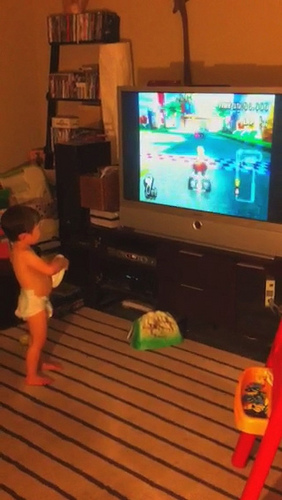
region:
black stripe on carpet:
[75, 310, 245, 372]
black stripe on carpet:
[52, 313, 237, 382]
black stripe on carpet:
[48, 325, 234, 399]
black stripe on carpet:
[46, 336, 232, 415]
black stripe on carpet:
[1, 363, 279, 498]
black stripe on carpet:
[0, 377, 230, 498]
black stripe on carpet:
[3, 401, 180, 497]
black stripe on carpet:
[0, 423, 127, 499]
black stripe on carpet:
[1, 452, 72, 499]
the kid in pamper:
[3, 206, 66, 386]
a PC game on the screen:
[123, 93, 280, 242]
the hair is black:
[1, 205, 42, 241]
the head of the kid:
[2, 206, 41, 246]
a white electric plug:
[265, 281, 275, 308]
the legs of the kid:
[24, 316, 61, 386]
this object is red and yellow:
[230, 327, 281, 496]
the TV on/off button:
[192, 221, 201, 229]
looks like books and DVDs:
[47, 12, 97, 143]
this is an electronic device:
[107, 243, 156, 267]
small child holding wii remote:
[1, 205, 72, 392]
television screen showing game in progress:
[115, 83, 279, 219]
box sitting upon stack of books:
[78, 165, 123, 230]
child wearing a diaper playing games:
[2, 205, 74, 388]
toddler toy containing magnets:
[230, 305, 281, 496]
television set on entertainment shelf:
[82, 76, 280, 352]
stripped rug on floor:
[1, 307, 273, 496]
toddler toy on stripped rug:
[124, 307, 190, 355]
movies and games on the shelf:
[43, 10, 119, 43]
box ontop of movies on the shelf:
[51, 117, 80, 130]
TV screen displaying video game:
[113, 83, 280, 259]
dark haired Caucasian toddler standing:
[3, 202, 69, 386]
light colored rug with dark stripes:
[10, 402, 228, 495]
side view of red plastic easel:
[229, 311, 281, 497]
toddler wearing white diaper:
[1, 201, 66, 325]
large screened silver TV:
[118, 83, 281, 258]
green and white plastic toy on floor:
[123, 307, 183, 352]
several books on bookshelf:
[32, 4, 118, 143]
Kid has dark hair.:
[3, 216, 41, 236]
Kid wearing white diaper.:
[7, 291, 55, 317]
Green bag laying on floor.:
[131, 315, 196, 346]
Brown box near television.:
[77, 170, 127, 212]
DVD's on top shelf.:
[42, 21, 121, 38]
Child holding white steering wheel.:
[50, 251, 82, 284]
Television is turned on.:
[152, 147, 223, 196]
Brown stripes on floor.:
[86, 412, 163, 489]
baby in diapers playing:
[3, 206, 73, 389]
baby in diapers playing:
[5, 199, 76, 395]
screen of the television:
[110, 92, 281, 219]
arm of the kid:
[40, 241, 87, 286]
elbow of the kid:
[38, 259, 60, 281]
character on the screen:
[171, 142, 223, 198]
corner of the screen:
[87, 67, 150, 121]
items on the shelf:
[32, 62, 111, 111]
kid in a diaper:
[0, 219, 83, 322]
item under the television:
[111, 290, 192, 354]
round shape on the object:
[179, 212, 216, 240]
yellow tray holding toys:
[226, 358, 278, 438]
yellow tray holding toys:
[229, 355, 280, 444]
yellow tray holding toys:
[225, 357, 280, 444]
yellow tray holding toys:
[224, 351, 279, 442]